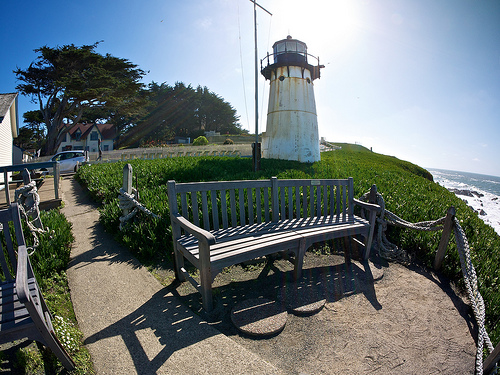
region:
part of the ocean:
[432, 160, 497, 227]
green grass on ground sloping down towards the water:
[111, 152, 499, 310]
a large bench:
[160, 169, 383, 315]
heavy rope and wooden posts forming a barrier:
[113, 158, 492, 373]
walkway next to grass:
[48, 168, 263, 371]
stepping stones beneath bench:
[203, 187, 399, 333]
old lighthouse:
[248, 23, 349, 179]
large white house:
[44, 114, 123, 159]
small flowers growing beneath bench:
[0, 211, 74, 365]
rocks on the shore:
[440, 176, 494, 227]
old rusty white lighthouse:
[244, 23, 343, 173]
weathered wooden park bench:
[148, 149, 403, 316]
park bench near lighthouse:
[3, 19, 490, 366]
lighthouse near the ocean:
[228, 7, 495, 251]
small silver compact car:
[32, 137, 106, 187]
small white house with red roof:
[50, 103, 141, 163]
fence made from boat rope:
[353, 170, 493, 372]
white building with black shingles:
[1, 82, 33, 192]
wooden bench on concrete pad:
[45, 151, 491, 371]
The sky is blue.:
[3, 2, 498, 167]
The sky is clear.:
[1, 3, 498, 180]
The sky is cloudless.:
[3, 2, 499, 177]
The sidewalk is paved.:
[53, 172, 279, 372]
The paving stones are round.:
[201, 224, 407, 343]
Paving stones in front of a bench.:
[205, 222, 400, 345]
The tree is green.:
[8, 37, 145, 169]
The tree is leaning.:
[11, 37, 147, 165]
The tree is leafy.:
[11, 39, 144, 165]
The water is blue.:
[416, 157, 498, 249]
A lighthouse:
[260, 31, 323, 163]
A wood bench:
[163, 176, 381, 291]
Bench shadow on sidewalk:
[100, 291, 212, 374]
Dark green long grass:
[145, 156, 226, 177]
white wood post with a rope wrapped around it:
[121, 161, 140, 226]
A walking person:
[95, 135, 105, 160]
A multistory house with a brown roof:
[65, 122, 117, 148]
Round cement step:
[230, 293, 286, 335]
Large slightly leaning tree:
[25, 42, 86, 152]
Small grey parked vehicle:
[46, 147, 89, 176]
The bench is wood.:
[148, 163, 385, 325]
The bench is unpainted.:
[158, 172, 375, 317]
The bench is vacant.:
[161, 166, 383, 318]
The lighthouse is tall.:
[253, 30, 328, 171]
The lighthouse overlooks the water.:
[247, 27, 499, 232]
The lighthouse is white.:
[252, 25, 337, 167]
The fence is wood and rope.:
[339, 177, 498, 372]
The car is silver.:
[32, 141, 101, 186]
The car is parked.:
[32, 135, 96, 188]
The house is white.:
[40, 116, 131, 173]